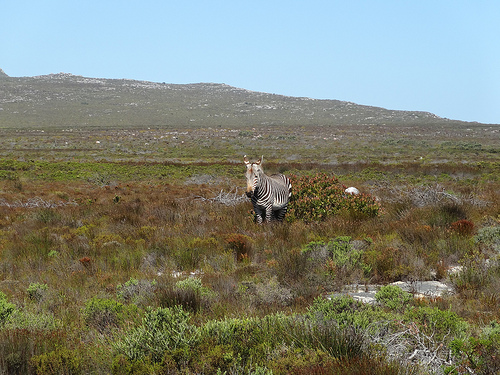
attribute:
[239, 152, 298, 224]
zebra — standing, large, black, white, striped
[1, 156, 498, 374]
field — grassy, green, brown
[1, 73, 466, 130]
mountain — brown, white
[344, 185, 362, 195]
object — white, large, round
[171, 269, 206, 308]
plant — green, leafy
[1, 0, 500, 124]
sky — light blue, blue, clear, pale blue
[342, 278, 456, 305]
rock — large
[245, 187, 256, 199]
nose — black, brown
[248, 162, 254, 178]
mark — brown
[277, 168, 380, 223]
bush — brown, green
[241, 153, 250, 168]
ear — striped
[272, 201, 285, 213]
underbelly — white